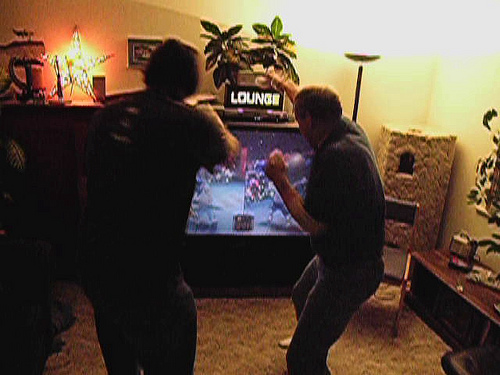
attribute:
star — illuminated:
[41, 21, 115, 103]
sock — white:
[274, 335, 295, 349]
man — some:
[272, 81, 383, 362]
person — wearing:
[72, 40, 252, 371]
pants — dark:
[91, 271, 198, 371]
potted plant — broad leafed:
[196, 9, 304, 121]